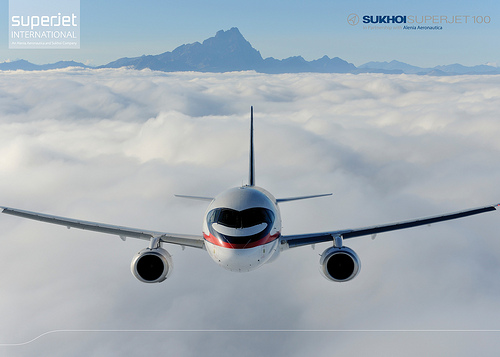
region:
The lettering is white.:
[3, 4, 85, 57]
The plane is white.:
[15, 103, 497, 282]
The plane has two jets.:
[107, 235, 371, 284]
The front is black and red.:
[185, 190, 297, 257]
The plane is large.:
[12, 119, 472, 309]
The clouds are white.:
[30, 65, 497, 353]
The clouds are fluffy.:
[7, 70, 448, 348]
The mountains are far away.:
[17, 17, 497, 78]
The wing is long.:
[2, 195, 206, 258]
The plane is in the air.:
[19, 126, 489, 284]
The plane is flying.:
[17, 120, 488, 316]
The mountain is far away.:
[15, 23, 476, 83]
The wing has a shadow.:
[294, 200, 497, 272]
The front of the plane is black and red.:
[187, 200, 297, 249]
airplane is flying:
[0, 105, 498, 282]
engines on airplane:
[130, 234, 362, 283]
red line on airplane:
[200, 230, 280, 249]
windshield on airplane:
[212, 207, 266, 226]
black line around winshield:
[205, 205, 275, 241]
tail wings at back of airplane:
[171, 105, 332, 201]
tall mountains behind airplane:
[0, 24, 498, 75]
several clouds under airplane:
[0, 65, 496, 355]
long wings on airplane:
[0, 201, 498, 247]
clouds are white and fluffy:
[0, 65, 499, 355]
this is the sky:
[96, 7, 115, 29]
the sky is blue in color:
[99, 3, 139, 28]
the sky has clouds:
[99, 30, 134, 55]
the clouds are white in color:
[87, 36, 113, 56]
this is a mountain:
[156, 25, 286, 69]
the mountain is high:
[148, 17, 271, 62]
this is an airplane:
[15, 110, 497, 300]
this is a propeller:
[131, 238, 178, 288]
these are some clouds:
[171, 276, 282, 323]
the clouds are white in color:
[238, 283, 295, 327]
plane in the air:
[70, 95, 468, 330]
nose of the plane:
[206, 205, 266, 280]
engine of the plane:
[310, 230, 370, 290]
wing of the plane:
[307, 180, 484, 286]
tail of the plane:
[225, 100, 282, 161]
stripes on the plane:
[197, 223, 267, 284]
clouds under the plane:
[43, 125, 153, 197]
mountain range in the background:
[106, 18, 431, 94]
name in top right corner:
[346, 11, 496, 46]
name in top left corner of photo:
[11, 7, 91, 72]